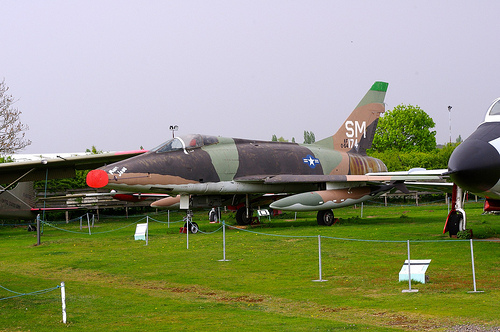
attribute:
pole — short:
[27, 205, 48, 248]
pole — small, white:
[463, 235, 480, 294]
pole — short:
[83, 210, 94, 235]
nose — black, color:
[438, 138, 498, 195]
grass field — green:
[298, 284, 400, 328]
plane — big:
[77, 76, 466, 244]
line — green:
[226, 220, 494, 250]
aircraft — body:
[61, 78, 456, 230]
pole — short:
[57, 279, 70, 326]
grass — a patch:
[21, 271, 86, 322]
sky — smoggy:
[11, 9, 483, 64]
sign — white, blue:
[133, 220, 148, 243]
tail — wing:
[308, 81, 388, 156]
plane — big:
[69, 38, 461, 243]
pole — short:
[456, 205, 485, 326]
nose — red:
[81, 165, 109, 191]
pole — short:
[358, 202, 364, 219]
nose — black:
[442, 140, 499, 192]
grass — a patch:
[299, 227, 376, 292]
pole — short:
[181, 219, 201, 247]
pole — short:
[452, 230, 484, 302]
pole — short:
[212, 217, 242, 267]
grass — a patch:
[129, 286, 173, 325]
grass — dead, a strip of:
[3, 216, 493, 330]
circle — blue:
[303, 153, 316, 169]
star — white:
[303, 149, 316, 165]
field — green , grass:
[3, 195, 499, 330]